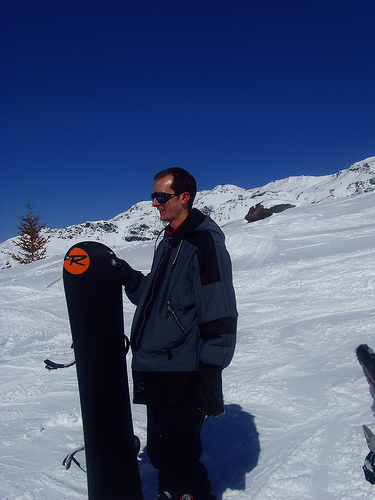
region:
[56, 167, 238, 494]
a man with a snow board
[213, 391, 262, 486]
a shadow of a man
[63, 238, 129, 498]
a black and orange snow board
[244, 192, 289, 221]
a rock covered in snow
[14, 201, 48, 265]
a brown tree on a slop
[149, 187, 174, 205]
a pair of sunglasses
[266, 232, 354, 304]
tracks in the snow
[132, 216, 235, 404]
a blue and black coat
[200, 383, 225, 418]
a black gloved hand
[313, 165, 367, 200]
a rocky snow cover hill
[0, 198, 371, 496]
Snow is covering the ground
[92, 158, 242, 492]
Man is in the foreground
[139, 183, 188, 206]
Man is wearing sunglasses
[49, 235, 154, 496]
Man is holding a snowboard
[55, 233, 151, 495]
The snowboard is black in color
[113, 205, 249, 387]
Man is wearing a gray coat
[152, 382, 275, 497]
Man is casting a shadow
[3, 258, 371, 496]
Tracks are in the snow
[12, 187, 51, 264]
A pine tree in the background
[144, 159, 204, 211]
Man has short dark hair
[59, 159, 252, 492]
a man with a snow board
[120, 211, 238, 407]
a gray and black coat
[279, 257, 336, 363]
tracks in the snow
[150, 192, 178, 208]
sun glasses on a head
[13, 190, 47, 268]
a tree in the snow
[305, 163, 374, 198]
a rocky snow covered mountain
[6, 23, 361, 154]
clear blue sky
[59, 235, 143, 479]
black snow board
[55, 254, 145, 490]
black snow board held by man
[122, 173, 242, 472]
man with big jacket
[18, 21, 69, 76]
blue sky with no clouds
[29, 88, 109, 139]
blue sky with no clouds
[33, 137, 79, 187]
blue sky with no clouds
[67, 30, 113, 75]
blue sky with no clouds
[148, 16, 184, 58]
blue sky with no clouds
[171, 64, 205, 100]
blue sky with no clouds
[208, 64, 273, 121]
blue sky with no clouds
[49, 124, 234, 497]
the man holding the snowboard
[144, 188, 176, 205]
the blue tinted glasses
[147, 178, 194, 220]
the man wearing a pair of sunglasses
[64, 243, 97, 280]
the orange round logo on the snowboard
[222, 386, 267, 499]
the shadow of the man in the snow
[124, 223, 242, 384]
the blue jacket on the man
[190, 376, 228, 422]
the glove on the mans hand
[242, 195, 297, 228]
a giant bolulder covered in snow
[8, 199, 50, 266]
a red tree sticking out over the hill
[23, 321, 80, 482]
the feet straps of the snowboard